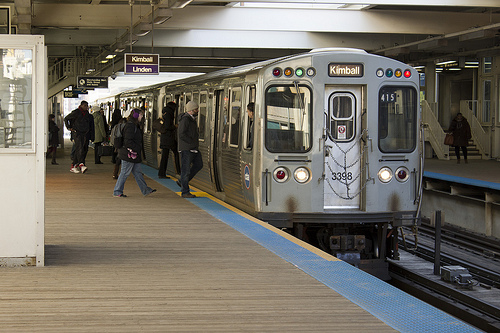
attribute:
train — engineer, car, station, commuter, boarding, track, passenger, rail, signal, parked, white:
[103, 30, 436, 271]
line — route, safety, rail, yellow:
[300, 53, 377, 92]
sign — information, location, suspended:
[0, 45, 58, 160]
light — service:
[278, 157, 321, 192]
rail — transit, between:
[173, 182, 265, 211]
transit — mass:
[64, 60, 224, 181]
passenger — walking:
[105, 93, 228, 257]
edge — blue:
[236, 229, 297, 267]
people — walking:
[45, 62, 190, 205]